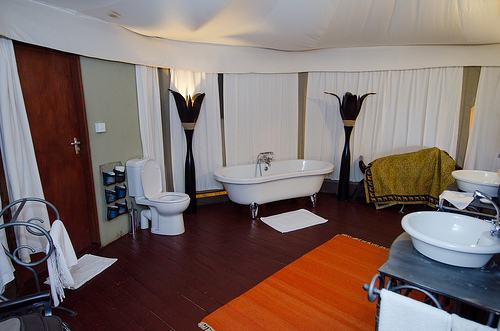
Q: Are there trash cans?
A: No, there are no trash cans.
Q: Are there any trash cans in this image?
A: No, there are no trash cans.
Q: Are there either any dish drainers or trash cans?
A: No, there are no trash cans or dish drainers.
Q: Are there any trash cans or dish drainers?
A: No, there are no trash cans or dish drainers.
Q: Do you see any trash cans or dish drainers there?
A: No, there are no trash cans or dish drainers.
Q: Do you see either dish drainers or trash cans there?
A: No, there are no trash cans or dish drainers.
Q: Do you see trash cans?
A: No, there are no trash cans.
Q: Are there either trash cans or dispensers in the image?
A: No, there are no trash cans or dispensers.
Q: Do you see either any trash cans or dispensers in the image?
A: No, there are no trash cans or dispensers.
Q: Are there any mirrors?
A: No, there are no mirrors.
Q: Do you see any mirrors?
A: No, there are no mirrors.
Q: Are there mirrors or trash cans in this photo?
A: No, there are no mirrors or trash cans.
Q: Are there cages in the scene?
A: No, there are no cages.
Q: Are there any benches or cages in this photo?
A: No, there are no cages or benches.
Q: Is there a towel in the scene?
A: Yes, there is a towel.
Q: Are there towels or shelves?
A: Yes, there is a towel.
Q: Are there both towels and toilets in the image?
A: Yes, there are both a towel and a toilet.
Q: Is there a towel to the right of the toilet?
A: Yes, there is a towel to the right of the toilet.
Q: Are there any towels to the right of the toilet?
A: Yes, there is a towel to the right of the toilet.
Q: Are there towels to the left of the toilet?
A: No, the towel is to the right of the toilet.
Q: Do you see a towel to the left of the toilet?
A: No, the towel is to the right of the toilet.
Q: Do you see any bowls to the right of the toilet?
A: No, there is a towel to the right of the toilet.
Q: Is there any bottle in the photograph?
A: No, there are no bottles.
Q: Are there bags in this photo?
A: No, there are no bags.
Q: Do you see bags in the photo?
A: No, there are no bags.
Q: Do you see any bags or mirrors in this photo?
A: No, there are no bags or mirrors.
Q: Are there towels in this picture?
A: Yes, there is a towel.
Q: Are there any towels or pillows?
A: Yes, there is a towel.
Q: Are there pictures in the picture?
A: No, there are no pictures.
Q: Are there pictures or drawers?
A: No, there are no pictures or drawers.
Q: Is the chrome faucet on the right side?
A: Yes, the faucet is on the right of the image.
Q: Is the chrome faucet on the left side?
A: No, the tap is on the right of the image.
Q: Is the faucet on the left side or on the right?
A: The faucet is on the right of the image.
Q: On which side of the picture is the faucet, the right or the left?
A: The faucet is on the right of the image.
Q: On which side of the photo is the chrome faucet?
A: The tap is on the right of the image.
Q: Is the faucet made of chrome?
A: Yes, the faucet is made of chrome.